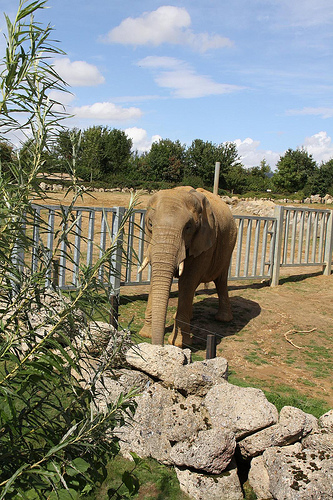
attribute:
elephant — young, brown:
[128, 179, 276, 346]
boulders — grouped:
[71, 324, 332, 494]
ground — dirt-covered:
[219, 285, 329, 402]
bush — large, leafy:
[2, 18, 67, 499]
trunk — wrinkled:
[140, 235, 172, 326]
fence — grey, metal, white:
[6, 208, 332, 278]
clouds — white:
[44, 11, 203, 134]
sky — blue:
[204, 18, 330, 124]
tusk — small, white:
[133, 259, 163, 281]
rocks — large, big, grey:
[71, 337, 329, 485]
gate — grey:
[276, 210, 330, 290]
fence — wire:
[123, 292, 216, 350]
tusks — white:
[130, 252, 186, 279]